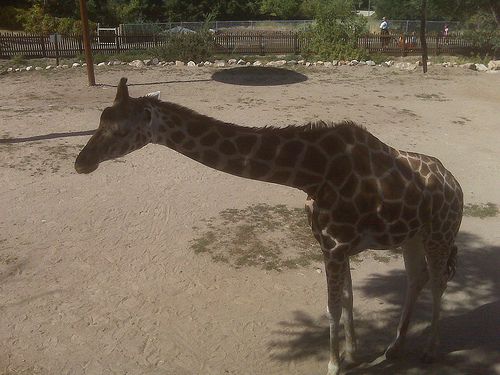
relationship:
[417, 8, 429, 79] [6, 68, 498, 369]
tree in ground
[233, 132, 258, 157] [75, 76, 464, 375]
spot on giraffe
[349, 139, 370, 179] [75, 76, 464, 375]
spot on giraffe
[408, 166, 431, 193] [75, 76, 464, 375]
spot on giraffe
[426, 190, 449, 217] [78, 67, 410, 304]
spot on giraffe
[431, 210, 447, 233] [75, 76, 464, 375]
spot on giraffe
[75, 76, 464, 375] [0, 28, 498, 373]
giraffe at zoo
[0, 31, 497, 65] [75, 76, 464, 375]
brown fence contain giraffe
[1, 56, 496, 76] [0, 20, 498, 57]
stones in front of fence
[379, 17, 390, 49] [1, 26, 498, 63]
mother on side of fence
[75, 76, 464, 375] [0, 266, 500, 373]
giraffe standing in dirt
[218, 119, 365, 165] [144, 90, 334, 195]
hair along neck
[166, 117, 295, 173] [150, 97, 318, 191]
spots along neck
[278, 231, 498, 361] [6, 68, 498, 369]
shadow on ground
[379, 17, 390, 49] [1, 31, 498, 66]
mother on other side fence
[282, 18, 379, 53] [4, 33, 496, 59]
bush in front fence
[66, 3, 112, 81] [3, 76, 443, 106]
brown pole in ground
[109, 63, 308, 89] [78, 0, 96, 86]
shadow of brown pole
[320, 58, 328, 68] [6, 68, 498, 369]
rock on ground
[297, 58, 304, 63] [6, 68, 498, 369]
rock on ground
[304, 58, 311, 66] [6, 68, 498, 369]
rock on ground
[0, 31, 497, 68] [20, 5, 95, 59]
brown fence behind trees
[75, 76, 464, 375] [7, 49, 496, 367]
giraffe on sand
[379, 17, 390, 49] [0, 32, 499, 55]
mother behind fence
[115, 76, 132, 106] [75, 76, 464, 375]
ear of giraffe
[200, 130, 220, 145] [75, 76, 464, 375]
spot on giraffe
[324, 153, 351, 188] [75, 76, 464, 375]
spot on giraffe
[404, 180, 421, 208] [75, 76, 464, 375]
spot on giraffe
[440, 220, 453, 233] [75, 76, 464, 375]
spot on giraffe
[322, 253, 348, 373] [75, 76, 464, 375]
leg of giraffe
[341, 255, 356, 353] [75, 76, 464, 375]
leg of giraffe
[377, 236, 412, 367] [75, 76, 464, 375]
leg of giraffe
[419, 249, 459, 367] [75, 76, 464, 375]
leg of giraffe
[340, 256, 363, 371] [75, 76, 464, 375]
leg of giraffe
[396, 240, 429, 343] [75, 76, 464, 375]
leg of giraffe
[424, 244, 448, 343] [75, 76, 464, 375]
leg of giraffe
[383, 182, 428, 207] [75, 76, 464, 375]
spot on giraffe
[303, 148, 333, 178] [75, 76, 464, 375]
spot on giraffe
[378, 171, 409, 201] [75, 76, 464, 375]
spot on giraffe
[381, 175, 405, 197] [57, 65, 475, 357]
spot on giraffe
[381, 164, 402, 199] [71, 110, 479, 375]
spot on giraffe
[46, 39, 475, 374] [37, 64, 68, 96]
giraffe under tree